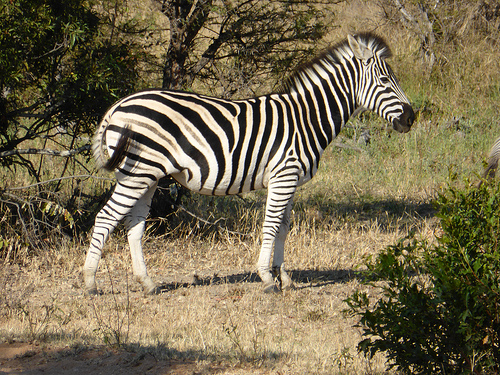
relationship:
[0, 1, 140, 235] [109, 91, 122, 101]
tree has leaf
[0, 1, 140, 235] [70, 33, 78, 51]
tree has leaf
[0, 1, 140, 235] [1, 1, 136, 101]
tree has leaves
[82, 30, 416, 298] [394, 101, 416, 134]
zebra has mouth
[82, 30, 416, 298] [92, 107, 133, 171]
zebra has tail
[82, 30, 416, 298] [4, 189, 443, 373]
zebra on ground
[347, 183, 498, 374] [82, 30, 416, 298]
bush front of zebra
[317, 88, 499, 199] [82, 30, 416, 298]
grass back of zebra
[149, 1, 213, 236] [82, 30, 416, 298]
tree trunk behind zebra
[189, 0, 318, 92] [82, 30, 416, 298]
branch behind zebra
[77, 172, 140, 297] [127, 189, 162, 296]
leg inches apart leg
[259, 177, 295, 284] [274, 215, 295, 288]
leg close to leg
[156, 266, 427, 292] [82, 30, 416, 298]
shadow under zebra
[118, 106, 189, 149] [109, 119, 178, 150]
stripe between stripe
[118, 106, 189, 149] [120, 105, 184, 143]
stripe between stripe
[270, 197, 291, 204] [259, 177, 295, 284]
stripe on leg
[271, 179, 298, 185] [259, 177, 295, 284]
stripe on leg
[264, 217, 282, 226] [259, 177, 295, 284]
stripe on leg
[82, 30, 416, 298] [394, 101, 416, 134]
zebra has muzzle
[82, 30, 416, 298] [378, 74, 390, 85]
zebra has eye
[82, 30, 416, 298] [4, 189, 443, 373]
zebra standing in grass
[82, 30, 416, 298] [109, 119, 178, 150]
zebra has stripe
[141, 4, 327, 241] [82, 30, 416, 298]
tree behind zebra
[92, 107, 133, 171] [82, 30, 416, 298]
tail of zebra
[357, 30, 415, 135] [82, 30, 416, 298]
head of zebra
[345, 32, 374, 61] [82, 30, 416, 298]
ear of zebra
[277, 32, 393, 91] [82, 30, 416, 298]
mane of zebra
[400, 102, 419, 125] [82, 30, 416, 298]
nose of zebra